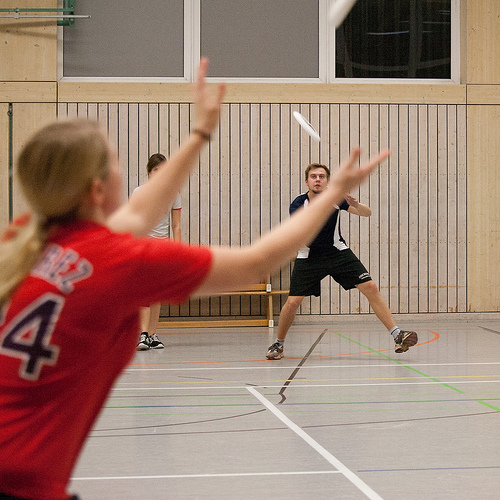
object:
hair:
[0, 118, 105, 301]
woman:
[133, 68, 181, 349]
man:
[266, 164, 416, 359]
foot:
[265, 342, 282, 359]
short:
[289, 249, 371, 298]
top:
[289, 191, 350, 258]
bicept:
[370, 176, 379, 242]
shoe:
[395, 331, 418, 353]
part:
[290, 369, 373, 481]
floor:
[0, 332, 499, 500]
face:
[309, 167, 327, 191]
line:
[280, 325, 328, 393]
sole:
[395, 331, 417, 353]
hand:
[334, 149, 389, 194]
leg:
[341, 248, 399, 338]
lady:
[0, 56, 391, 500]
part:
[348, 203, 371, 217]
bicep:
[340, 201, 349, 211]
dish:
[293, 111, 320, 142]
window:
[199, 0, 320, 76]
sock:
[390, 326, 400, 338]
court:
[0, 312, 500, 498]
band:
[355, 201, 358, 208]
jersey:
[0, 214, 209, 498]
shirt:
[132, 185, 182, 237]